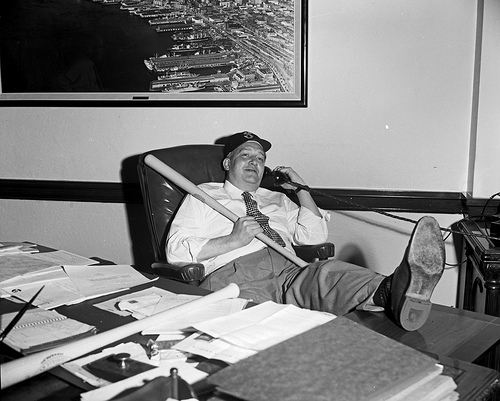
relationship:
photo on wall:
[130, 21, 303, 101] [413, 46, 416, 47]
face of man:
[229, 131, 277, 186] [224, 136, 352, 293]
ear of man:
[221, 150, 238, 173] [224, 136, 352, 293]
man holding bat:
[224, 136, 352, 293] [149, 146, 223, 196]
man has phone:
[224, 136, 352, 293] [270, 172, 289, 184]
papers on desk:
[48, 262, 103, 288] [80, 307, 111, 316]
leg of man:
[301, 278, 365, 302] [224, 136, 352, 293]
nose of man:
[245, 159, 257, 167] [224, 136, 352, 293]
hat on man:
[240, 129, 264, 146] [224, 136, 352, 293]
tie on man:
[243, 194, 250, 211] [224, 136, 352, 293]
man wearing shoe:
[224, 136, 352, 293] [397, 229, 430, 332]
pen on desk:
[1, 298, 48, 312] [80, 307, 111, 316]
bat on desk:
[149, 146, 223, 196] [80, 307, 111, 316]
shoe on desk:
[397, 229, 430, 332] [80, 307, 111, 316]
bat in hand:
[149, 146, 223, 196] [231, 222, 260, 241]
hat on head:
[240, 129, 264, 146] [249, 140, 260, 149]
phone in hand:
[270, 172, 289, 184] [231, 222, 260, 241]